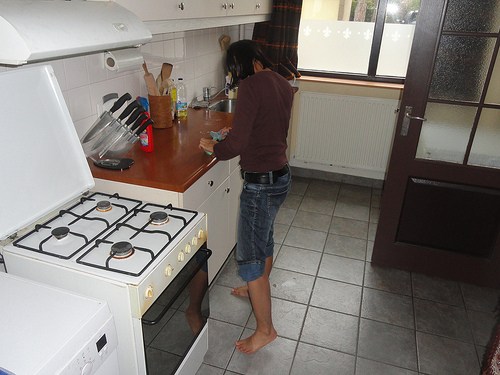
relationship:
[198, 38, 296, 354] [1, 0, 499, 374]
woman inside kitchen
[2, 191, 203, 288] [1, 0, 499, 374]
stove inside kitchen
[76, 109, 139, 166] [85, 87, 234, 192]
knife block on top of counter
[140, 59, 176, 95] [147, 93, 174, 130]
cooking utensils inside of container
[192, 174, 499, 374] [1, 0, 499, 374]
floor inside kitchen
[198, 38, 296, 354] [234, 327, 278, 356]
woman has left foot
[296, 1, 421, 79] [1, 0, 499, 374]
window inside of kitchen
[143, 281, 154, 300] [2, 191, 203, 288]
knob on front of stove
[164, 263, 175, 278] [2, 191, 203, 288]
knob on front of stove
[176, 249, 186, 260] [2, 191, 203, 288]
knob on front of stove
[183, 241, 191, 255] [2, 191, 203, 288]
knob on front of stove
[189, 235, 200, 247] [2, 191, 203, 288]
knob on front of stove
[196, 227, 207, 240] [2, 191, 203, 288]
knob on front of stove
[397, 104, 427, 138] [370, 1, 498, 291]
handle on front of door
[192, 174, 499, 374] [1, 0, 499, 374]
floor inside of kitchen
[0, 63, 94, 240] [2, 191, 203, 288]
cover open on stove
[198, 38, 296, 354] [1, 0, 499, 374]
woman inside of kitchen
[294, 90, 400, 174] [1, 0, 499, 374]
wall heater inside of kitchen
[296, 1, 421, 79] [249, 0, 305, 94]
window has curtains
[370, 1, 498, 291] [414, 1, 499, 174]
door has windows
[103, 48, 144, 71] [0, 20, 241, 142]
towel dispenser attached to wall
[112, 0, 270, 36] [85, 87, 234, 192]
cabinets over counter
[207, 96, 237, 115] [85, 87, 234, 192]
sink built in counter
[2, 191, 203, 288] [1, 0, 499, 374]
stove inside of kitchen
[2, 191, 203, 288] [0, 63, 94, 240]
stove has cover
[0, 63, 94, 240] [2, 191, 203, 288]
cover open over stove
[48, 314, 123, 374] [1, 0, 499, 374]
dishwasher inside of kitchen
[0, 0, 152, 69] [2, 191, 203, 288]
range hood above stove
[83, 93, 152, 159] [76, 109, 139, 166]
knives set in knife block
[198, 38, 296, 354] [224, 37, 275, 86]
woman has hair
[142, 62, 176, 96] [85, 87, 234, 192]
cooking utensils on top of counter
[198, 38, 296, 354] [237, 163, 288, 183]
woman wearing belt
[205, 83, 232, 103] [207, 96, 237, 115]
faucet behind sink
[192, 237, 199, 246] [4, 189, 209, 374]
knob on front of oven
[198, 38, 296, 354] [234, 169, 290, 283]
woman wearing jeans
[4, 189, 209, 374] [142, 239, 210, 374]
oven has door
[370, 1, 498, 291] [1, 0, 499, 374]
door open in back of kitchen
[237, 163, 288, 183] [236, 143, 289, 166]
belt around waist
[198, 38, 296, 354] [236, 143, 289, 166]
woman has waist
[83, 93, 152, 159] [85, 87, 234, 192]
knives on top of counter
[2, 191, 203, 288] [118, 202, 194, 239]
stove has burner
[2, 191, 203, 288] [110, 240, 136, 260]
stove has burner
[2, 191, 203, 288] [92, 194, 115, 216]
stove has burner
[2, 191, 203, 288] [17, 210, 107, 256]
stove has burner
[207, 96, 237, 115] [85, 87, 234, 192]
sink inside of counter